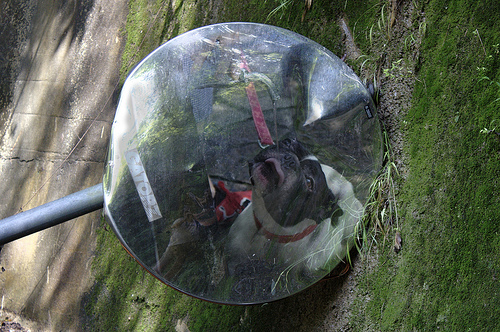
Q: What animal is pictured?
A: A dog.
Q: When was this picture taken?
A: During the daytime.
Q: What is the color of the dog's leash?
A: Red.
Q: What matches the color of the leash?
A: His collar.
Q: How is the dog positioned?
A: It is sitting.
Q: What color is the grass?
A: Green.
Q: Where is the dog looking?
A: Upward.